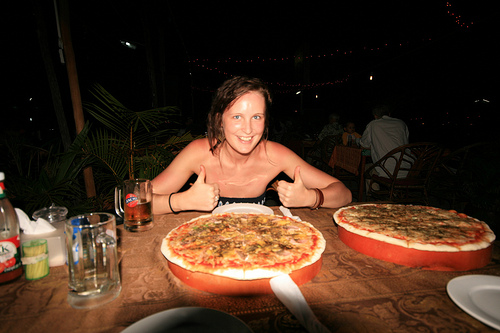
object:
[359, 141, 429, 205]
chair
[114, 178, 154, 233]
glass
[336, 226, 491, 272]
pizza tray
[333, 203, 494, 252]
pizza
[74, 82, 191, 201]
plant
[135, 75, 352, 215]
girl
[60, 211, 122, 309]
mug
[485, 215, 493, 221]
ground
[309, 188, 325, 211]
braclets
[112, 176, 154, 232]
glass mug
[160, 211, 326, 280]
pizza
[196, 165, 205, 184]
thumb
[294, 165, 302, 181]
thumb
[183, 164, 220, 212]
hand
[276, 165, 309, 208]
hand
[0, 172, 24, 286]
bottle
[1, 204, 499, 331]
table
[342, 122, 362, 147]
child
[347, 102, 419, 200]
adult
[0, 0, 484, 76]
background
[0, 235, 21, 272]
label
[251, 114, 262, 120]
eye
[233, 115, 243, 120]
eye